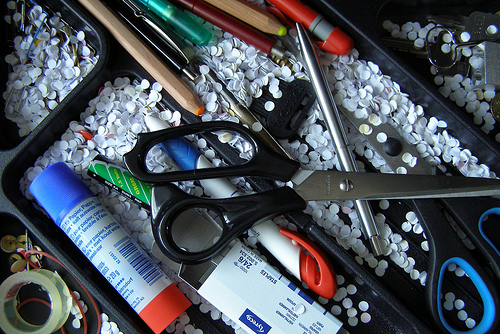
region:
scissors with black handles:
[115, 119, 499, 264]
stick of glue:
[20, 160, 196, 332]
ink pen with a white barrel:
[137, 102, 344, 304]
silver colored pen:
[294, 22, 389, 263]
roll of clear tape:
[2, 250, 82, 332]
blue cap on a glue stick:
[28, 156, 95, 224]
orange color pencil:
[84, 0, 208, 118]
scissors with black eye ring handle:
[120, 115, 498, 275]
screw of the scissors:
[336, 177, 355, 192]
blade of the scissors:
[360, 163, 498, 203]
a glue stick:
[26, 155, 194, 332]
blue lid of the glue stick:
[26, 157, 101, 233]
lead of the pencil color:
[191, 103, 206, 117]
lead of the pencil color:
[276, 24, 287, 37]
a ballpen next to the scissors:
[290, 18, 401, 261]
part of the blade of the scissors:
[333, 85, 425, 172]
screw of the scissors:
[380, 133, 405, 158]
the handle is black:
[144, 117, 296, 236]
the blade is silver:
[302, 161, 497, 211]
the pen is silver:
[294, 42, 387, 267]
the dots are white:
[85, 95, 143, 149]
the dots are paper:
[74, 97, 145, 160]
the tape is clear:
[5, 257, 70, 332]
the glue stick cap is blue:
[32, 164, 94, 224]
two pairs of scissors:
[128, 82, 492, 312]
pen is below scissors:
[197, 49, 496, 257]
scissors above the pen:
[146, 31, 375, 266]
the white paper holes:
[0, 0, 499, 333]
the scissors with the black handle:
[123, 119, 498, 263]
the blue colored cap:
[30, 160, 98, 226]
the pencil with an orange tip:
[80, 0, 205, 118]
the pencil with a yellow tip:
[203, 0, 288, 36]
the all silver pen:
[294, 20, 384, 256]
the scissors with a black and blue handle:
[335, 90, 497, 332]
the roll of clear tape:
[3, 268, 70, 332]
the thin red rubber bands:
[13, 246, 101, 332]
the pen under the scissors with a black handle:
[122, 110, 498, 299]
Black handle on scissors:
[126, 118, 309, 259]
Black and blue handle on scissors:
[418, 174, 498, 331]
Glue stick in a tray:
[30, 163, 188, 328]